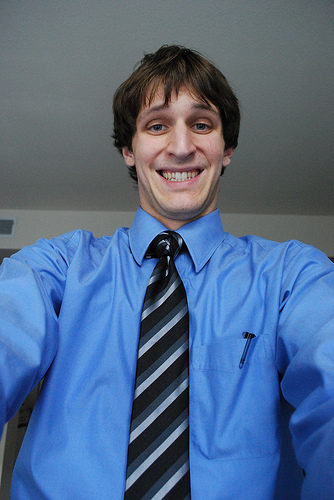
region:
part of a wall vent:
[1, 216, 16, 236]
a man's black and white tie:
[121, 232, 207, 498]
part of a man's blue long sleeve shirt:
[0, 201, 333, 498]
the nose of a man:
[166, 115, 196, 160]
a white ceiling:
[1, 0, 332, 220]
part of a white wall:
[222, 213, 332, 252]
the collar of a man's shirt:
[125, 202, 226, 272]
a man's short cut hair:
[110, 42, 242, 182]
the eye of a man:
[187, 120, 213, 136]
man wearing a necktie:
[104, 218, 204, 453]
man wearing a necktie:
[126, 213, 248, 363]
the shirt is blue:
[185, 238, 246, 330]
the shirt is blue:
[46, 306, 178, 454]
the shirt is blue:
[90, 242, 221, 295]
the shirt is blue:
[196, 297, 263, 448]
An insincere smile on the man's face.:
[153, 164, 210, 187]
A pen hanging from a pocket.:
[237, 326, 257, 371]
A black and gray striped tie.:
[128, 228, 196, 498]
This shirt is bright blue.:
[76, 298, 126, 405]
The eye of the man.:
[143, 115, 171, 137]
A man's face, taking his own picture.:
[79, 35, 247, 239]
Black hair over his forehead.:
[136, 46, 205, 107]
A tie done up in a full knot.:
[147, 230, 187, 261]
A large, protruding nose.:
[165, 120, 196, 161]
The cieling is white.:
[13, 143, 82, 220]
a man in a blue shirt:
[0, 43, 333, 498]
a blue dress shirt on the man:
[1, 201, 332, 498]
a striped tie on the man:
[123, 229, 190, 498]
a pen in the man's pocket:
[237, 328, 253, 368]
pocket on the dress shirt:
[190, 331, 282, 458]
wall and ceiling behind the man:
[0, 0, 333, 261]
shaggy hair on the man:
[111, 43, 239, 189]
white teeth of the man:
[156, 166, 203, 181]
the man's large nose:
[165, 114, 196, 159]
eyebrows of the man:
[139, 100, 216, 118]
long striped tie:
[128, 240, 198, 498]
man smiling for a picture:
[88, 34, 259, 232]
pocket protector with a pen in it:
[189, 327, 280, 459]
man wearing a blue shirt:
[2, 20, 331, 498]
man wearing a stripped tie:
[1, 31, 332, 497]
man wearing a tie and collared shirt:
[4, 26, 319, 494]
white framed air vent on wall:
[0, 214, 19, 239]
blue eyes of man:
[140, 112, 221, 137]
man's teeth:
[153, 162, 211, 184]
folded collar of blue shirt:
[119, 204, 236, 270]